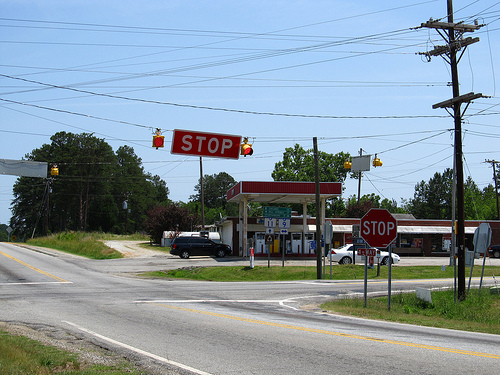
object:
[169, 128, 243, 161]
sign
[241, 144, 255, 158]
light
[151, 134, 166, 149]
light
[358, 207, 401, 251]
sign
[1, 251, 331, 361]
intersection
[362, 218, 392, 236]
stop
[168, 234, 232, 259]
suv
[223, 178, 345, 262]
gas station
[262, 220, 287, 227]
signs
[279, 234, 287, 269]
pole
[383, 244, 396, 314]
pole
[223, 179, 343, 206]
awning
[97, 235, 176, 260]
road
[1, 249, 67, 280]
line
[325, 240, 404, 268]
car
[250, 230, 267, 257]
pump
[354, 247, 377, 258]
4 way sign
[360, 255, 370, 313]
pole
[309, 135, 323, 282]
pole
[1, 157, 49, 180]
sign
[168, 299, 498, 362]
line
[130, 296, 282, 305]
line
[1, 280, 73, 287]
line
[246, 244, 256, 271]
pole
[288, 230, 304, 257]
pump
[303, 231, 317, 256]
pump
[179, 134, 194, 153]
letter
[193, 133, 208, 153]
letter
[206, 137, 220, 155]
letter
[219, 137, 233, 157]
letter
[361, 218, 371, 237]
letter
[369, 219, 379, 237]
letter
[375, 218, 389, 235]
letter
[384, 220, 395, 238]
letter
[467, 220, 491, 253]
sign